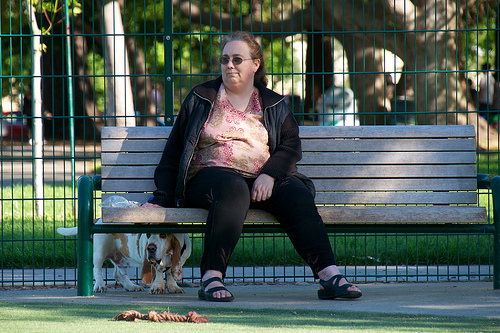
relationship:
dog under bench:
[57, 208, 194, 297] [72, 121, 493, 298]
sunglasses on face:
[223, 53, 245, 67] [192, 40, 266, 99]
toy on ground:
[112, 306, 211, 323] [3, 284, 498, 329]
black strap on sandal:
[200, 276, 227, 288] [191, 269, 241, 299]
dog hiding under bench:
[57, 208, 194, 297] [72, 121, 493, 298]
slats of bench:
[99, 123, 480, 137] [89, 101, 495, 248]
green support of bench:
[71, 175, 98, 300] [72, 121, 493, 298]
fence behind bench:
[1, 0, 498, 287] [72, 121, 493, 298]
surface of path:
[394, 283, 425, 295] [357, 268, 480, 321]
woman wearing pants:
[152, 25, 360, 300] [175, 167, 339, 273]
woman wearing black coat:
[152, 25, 360, 300] [152, 77, 307, 207]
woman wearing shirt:
[152, 25, 360, 300] [198, 79, 270, 171]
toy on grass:
[112, 306, 211, 323] [8, 277, 498, 329]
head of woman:
[215, 65, 268, 84] [165, 29, 378, 316]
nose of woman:
[226, 61, 235, 70] [152, 25, 360, 300]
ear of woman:
[253, 59, 262, 69] [152, 25, 360, 300]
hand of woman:
[250, 173, 277, 204] [152, 88, 385, 306]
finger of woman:
[264, 186, 274, 198] [152, 25, 360, 300]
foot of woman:
[196, 267, 232, 303] [155, 57, 385, 321]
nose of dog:
[221, 60, 242, 68] [89, 209, 196, 292]